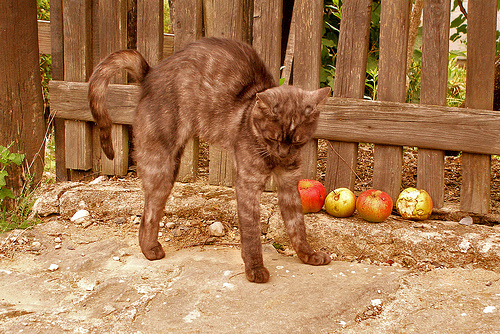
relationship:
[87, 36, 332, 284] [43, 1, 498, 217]
cat on fence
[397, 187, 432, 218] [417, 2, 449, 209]
apple leaning on wooden post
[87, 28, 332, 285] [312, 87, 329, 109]
cat leaning on ear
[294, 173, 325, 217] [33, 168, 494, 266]
apple on ledge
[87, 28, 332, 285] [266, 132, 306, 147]
cat has eyes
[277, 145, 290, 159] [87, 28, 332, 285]
nose of cat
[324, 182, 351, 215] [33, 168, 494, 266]
apple on ledge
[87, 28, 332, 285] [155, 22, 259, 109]
cat arching back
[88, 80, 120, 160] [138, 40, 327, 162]
tail on cat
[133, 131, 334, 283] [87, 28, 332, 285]
legs on cat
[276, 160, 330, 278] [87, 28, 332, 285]
legs on cat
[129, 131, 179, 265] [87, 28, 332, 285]
legs on cat